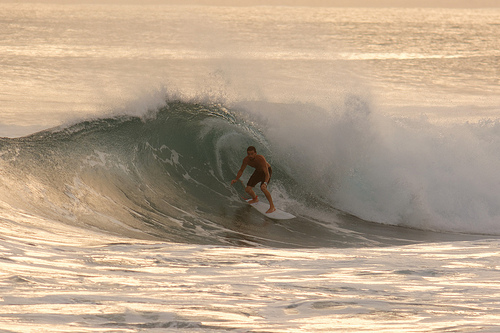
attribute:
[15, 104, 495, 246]
wave — large, tall, white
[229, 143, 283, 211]
man — balancing, riding, shirtless, surfing, standing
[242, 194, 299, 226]
board — floating, white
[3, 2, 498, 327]
water — splashing, calm, reflecting, foaming, gray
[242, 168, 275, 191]
shorts — red, black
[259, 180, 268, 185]
wristband — white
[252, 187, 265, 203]
rope — tied